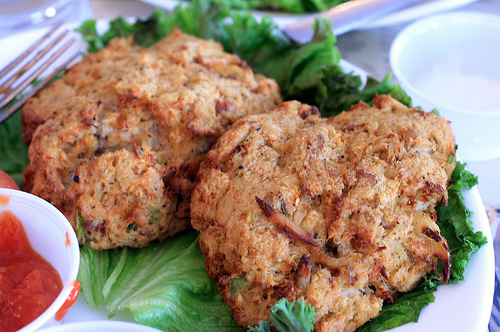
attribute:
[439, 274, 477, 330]
plate — white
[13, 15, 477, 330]
lettuce — green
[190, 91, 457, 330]
crab cake — brown